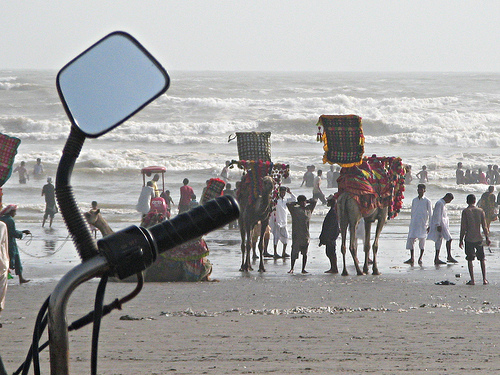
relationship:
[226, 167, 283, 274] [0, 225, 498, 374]
camel sitting on beach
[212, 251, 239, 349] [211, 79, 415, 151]
sand meeting water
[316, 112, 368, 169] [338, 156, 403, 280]
seat on camel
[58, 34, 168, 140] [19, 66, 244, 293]
glass attached to handle bar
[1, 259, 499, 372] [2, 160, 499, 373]
sand on beach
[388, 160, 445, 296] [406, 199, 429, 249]
man wearing tunic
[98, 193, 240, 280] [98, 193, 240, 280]
grip on grip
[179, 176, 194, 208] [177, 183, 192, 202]
person wearing red shirt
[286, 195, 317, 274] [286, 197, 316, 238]
man wearing brown tunic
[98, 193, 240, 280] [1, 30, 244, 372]
grip on motorcycle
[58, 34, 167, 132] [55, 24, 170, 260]
glass on mirror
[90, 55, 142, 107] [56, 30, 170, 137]
sky on mirror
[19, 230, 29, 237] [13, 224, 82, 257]
hand holding tether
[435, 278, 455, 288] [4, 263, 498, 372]
trash on shore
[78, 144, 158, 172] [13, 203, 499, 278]
wave breaking on shore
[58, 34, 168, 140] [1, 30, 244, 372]
glass on motorcycle